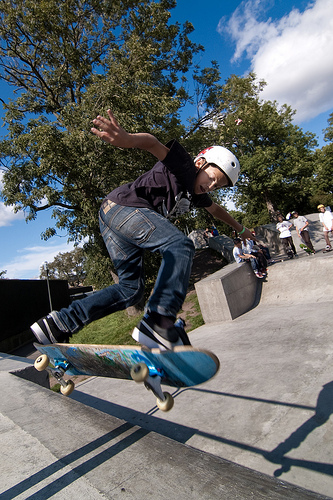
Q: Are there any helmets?
A: Yes, there is a helmet.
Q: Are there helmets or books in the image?
A: Yes, there is a helmet.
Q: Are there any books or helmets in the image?
A: Yes, there is a helmet.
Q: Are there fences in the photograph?
A: No, there are no fences.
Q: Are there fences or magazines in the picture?
A: No, there are no fences or magazines.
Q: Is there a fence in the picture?
A: No, there are no fences.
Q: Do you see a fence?
A: No, there are no fences.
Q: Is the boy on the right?
A: Yes, the boy is on the right of the image.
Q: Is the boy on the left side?
A: No, the boy is on the right of the image.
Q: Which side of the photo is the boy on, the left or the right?
A: The boy is on the right of the image.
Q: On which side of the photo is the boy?
A: The boy is on the right of the image.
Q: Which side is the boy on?
A: The boy is on the right of the image.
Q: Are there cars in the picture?
A: No, there are no cars.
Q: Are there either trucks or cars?
A: No, there are no cars or trucks.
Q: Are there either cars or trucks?
A: No, there are no cars or trucks.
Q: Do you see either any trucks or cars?
A: No, there are no cars or trucks.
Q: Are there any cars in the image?
A: No, there are no cars.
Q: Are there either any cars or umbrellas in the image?
A: No, there are no cars or umbrellas.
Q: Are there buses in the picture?
A: No, there are no buses.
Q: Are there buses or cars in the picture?
A: No, there are no buses or cars.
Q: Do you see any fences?
A: No, there are no fences.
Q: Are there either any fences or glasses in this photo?
A: No, there are no fences or glasses.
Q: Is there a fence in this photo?
A: No, there are no fences.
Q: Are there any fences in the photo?
A: No, there are no fences.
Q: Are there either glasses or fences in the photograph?
A: No, there are no fences or glasses.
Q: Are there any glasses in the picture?
A: No, there are no glasses.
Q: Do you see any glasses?
A: No, there are no glasses.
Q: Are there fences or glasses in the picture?
A: No, there are no glasses or fences.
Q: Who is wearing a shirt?
A: The man is wearing a shirt.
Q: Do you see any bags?
A: No, there are no bags.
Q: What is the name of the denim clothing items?
A: The clothing items are jeans.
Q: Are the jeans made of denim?
A: Yes, the jeans are made of denim.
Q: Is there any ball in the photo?
A: No, there are no balls.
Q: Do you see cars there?
A: No, there are no cars.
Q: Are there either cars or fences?
A: No, there are no cars or fences.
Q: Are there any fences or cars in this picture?
A: No, there are no cars or fences.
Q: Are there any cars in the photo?
A: No, there are no cars.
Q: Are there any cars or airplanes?
A: No, there are no cars or airplanes.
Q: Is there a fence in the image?
A: No, there are no fences.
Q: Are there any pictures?
A: No, there are no pictures.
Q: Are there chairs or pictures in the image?
A: No, there are no pictures or chairs.